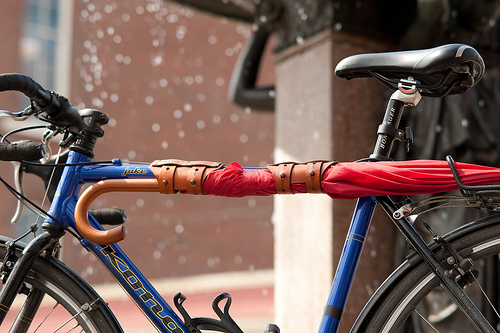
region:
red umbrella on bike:
[131, 164, 454, 251]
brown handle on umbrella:
[73, 174, 121, 251]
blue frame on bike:
[30, 142, 336, 330]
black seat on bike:
[326, 20, 478, 115]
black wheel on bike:
[386, 246, 495, 305]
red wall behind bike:
[74, 43, 284, 275]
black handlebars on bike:
[9, 74, 104, 164]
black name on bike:
[94, 238, 181, 325]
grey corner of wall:
[241, 37, 346, 317]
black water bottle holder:
[171, 287, 256, 329]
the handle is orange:
[71, 167, 205, 267]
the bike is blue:
[304, 239, 347, 331]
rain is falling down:
[75, 52, 235, 154]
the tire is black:
[386, 265, 415, 307]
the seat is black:
[352, 23, 484, 108]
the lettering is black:
[101, 240, 168, 332]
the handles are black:
[1, 93, 118, 139]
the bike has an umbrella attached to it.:
[18, 76, 313, 220]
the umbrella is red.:
[216, 157, 442, 207]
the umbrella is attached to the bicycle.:
[18, 148, 474, 233]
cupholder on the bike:
[164, 286, 261, 330]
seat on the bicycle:
[334, 35, 497, 96]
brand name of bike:
[105, 245, 182, 330]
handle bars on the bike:
[0, 77, 114, 141]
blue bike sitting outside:
[1, 42, 498, 328]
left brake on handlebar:
[0, 102, 48, 129]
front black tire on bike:
[45, 261, 117, 331]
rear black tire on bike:
[362, 265, 432, 331]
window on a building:
[19, 4, 65, 92]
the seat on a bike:
[336, 15, 496, 134]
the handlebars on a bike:
[6, 51, 132, 153]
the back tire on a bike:
[365, 223, 497, 322]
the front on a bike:
[7, 220, 183, 320]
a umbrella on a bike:
[21, 78, 468, 305]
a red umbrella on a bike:
[78, 103, 473, 263]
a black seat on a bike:
[323, 37, 486, 116]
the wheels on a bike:
[5, 158, 495, 323]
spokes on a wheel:
[8, 273, 133, 324]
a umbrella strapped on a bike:
[58, 143, 437, 250]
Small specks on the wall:
[75, 64, 110, 85]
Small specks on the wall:
[73, 32, 112, 62]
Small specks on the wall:
[82, 5, 124, 39]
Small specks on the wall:
[115, 1, 192, 53]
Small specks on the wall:
[181, 14, 242, 61]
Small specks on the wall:
[133, 39, 186, 101]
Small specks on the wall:
[175, 95, 227, 140]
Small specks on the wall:
[107, 73, 197, 146]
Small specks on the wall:
[145, 208, 195, 265]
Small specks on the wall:
[190, 216, 264, 273]